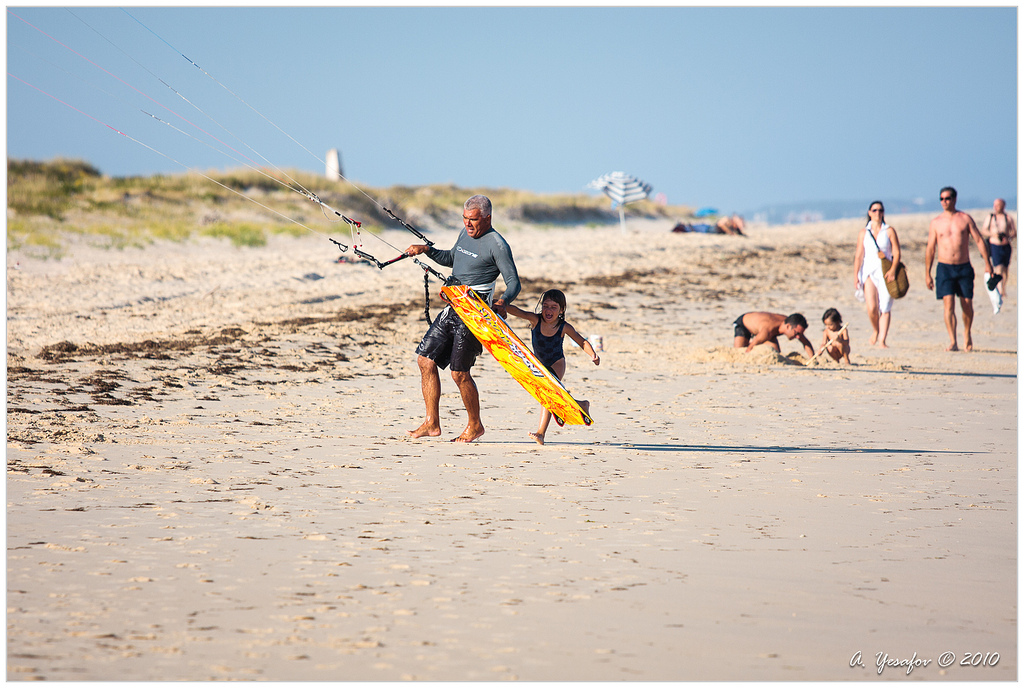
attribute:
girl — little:
[499, 284, 595, 441]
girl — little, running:
[489, 283, 606, 448]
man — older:
[400, 195, 518, 442]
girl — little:
[815, 305, 851, 369]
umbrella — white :
[584, 170, 662, 225]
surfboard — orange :
[441, 277, 594, 434]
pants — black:
[933, 259, 972, 301]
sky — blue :
[4, 0, 1011, 215]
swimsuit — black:
[514, 312, 581, 373]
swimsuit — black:
[532, 309, 576, 385]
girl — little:
[494, 290, 611, 440]